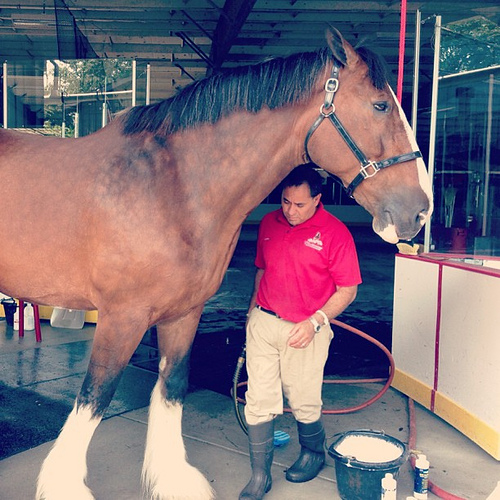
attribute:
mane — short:
[109, 44, 384, 131]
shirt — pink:
[255, 202, 362, 322]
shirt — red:
[248, 204, 365, 328]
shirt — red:
[263, 220, 341, 291]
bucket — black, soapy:
[320, 423, 410, 498]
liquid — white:
[331, 430, 404, 464]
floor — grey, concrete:
[6, 350, 56, 417]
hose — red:
[378, 372, 400, 395]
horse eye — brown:
[372, 102, 387, 112]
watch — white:
[305, 313, 322, 335]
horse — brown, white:
[36, 24, 451, 427]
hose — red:
[334, 315, 408, 475]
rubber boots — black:
[240, 417, 282, 497]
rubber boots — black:
[284, 414, 331, 483]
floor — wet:
[175, 383, 249, 448]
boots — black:
[227, 411, 334, 498]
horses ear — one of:
[324, 20, 361, 72]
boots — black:
[233, 419, 330, 499]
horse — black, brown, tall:
[22, 40, 432, 497]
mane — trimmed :
[126, 24, 398, 159]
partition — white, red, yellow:
[389, 1, 499, 459]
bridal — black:
[303, 64, 428, 216]